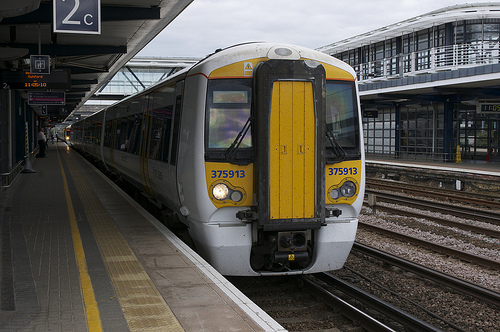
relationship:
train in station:
[61, 37, 369, 289] [1, 3, 499, 331]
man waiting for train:
[35, 123, 49, 157] [61, 37, 369, 289]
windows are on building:
[349, 23, 477, 84] [351, 2, 499, 162]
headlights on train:
[207, 177, 358, 210] [61, 37, 369, 289]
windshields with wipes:
[208, 79, 358, 161] [222, 114, 352, 163]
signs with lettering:
[51, 2, 104, 37] [58, 0, 97, 27]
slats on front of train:
[256, 219, 327, 232] [195, 37, 367, 281]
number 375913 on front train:
[326, 164, 361, 177] [195, 37, 367, 281]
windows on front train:
[208, 79, 358, 161] [195, 37, 367, 281]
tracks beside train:
[359, 207, 496, 328] [61, 37, 369, 289]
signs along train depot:
[51, 0, 104, 36] [4, 4, 189, 331]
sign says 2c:
[51, 2, 104, 37] [58, 0, 97, 27]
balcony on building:
[356, 60, 499, 96] [351, 2, 499, 162]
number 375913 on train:
[326, 164, 361, 177] [61, 37, 369, 289]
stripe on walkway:
[66, 147, 184, 331] [27, 140, 175, 332]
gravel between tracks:
[359, 207, 496, 328] [367, 178, 483, 327]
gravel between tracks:
[359, 207, 496, 328] [379, 176, 481, 328]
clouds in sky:
[191, 3, 373, 39] [212, 0, 338, 40]